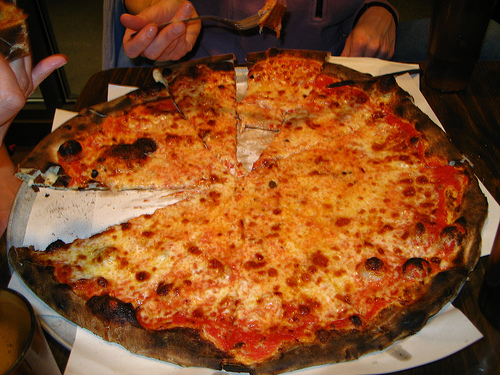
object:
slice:
[147, 51, 242, 176]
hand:
[115, 2, 204, 62]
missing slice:
[6, 183, 196, 256]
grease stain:
[386, 341, 414, 361]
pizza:
[252, 0, 290, 38]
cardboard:
[3, 53, 498, 373]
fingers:
[117, 4, 159, 32]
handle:
[126, 13, 223, 40]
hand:
[0, 47, 67, 143]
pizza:
[233, 50, 322, 130]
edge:
[98, 328, 206, 365]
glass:
[0, 287, 40, 374]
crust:
[162, 53, 239, 85]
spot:
[82, 291, 144, 330]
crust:
[12, 80, 170, 180]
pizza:
[13, 80, 238, 192]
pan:
[6, 82, 482, 375]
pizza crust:
[10, 164, 487, 373]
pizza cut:
[8, 183, 216, 256]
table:
[0, 67, 499, 373]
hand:
[337, 5, 396, 60]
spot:
[130, 135, 156, 155]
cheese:
[44, 56, 462, 361]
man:
[112, 0, 409, 73]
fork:
[129, 5, 274, 39]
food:
[252, 0, 287, 37]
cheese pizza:
[5, 164, 489, 372]